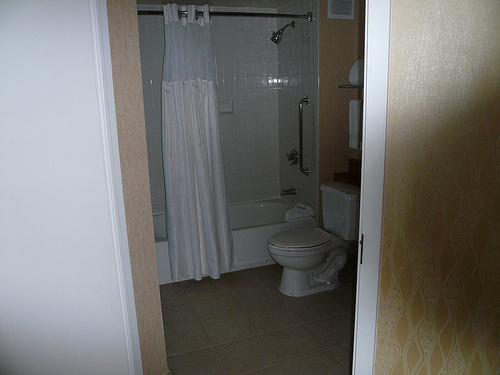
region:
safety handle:
[295, 92, 311, 177]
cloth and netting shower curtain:
[160, 3, 237, 283]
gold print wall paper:
[373, 0, 498, 374]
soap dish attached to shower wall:
[216, 97, 233, 114]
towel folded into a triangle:
[281, 200, 316, 225]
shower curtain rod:
[136, 9, 312, 21]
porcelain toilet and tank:
[265, 177, 358, 297]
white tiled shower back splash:
[136, 2, 321, 214]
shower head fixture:
[266, 18, 298, 47]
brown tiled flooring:
[159, 260, 357, 374]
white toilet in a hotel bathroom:
[285, 235, 342, 288]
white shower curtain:
[167, 7, 207, 265]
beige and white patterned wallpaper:
[404, 136, 481, 365]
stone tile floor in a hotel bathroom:
[180, 296, 342, 348]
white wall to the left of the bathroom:
[13, 84, 94, 364]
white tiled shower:
[235, 55, 277, 181]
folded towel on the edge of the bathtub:
[284, 202, 315, 219]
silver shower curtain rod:
[209, 9, 314, 19]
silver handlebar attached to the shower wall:
[299, 97, 308, 176]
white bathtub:
[235, 202, 266, 254]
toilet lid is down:
[266, 219, 332, 259]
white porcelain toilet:
[260, 155, 365, 317]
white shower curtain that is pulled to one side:
[148, 9, 256, 284]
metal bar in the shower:
[293, 96, 314, 179]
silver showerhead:
[265, 21, 297, 47]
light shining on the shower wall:
[262, 73, 292, 90]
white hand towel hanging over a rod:
[339, 96, 366, 149]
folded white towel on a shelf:
[337, 56, 365, 92]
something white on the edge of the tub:
[275, 196, 317, 222]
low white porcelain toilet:
[255, 219, 357, 327]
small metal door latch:
[354, 218, 374, 273]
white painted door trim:
[340, 7, 410, 373]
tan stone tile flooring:
[186, 292, 308, 369]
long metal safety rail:
[287, 94, 314, 179]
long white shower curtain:
[147, 7, 241, 291]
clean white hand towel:
[340, 97, 362, 149]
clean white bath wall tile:
[232, 43, 306, 110]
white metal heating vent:
[319, 1, 357, 33]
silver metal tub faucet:
[273, 183, 299, 201]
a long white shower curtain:
[155, 43, 240, 276]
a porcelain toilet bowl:
[264, 221, 343, 297]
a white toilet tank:
[316, 174, 357, 239]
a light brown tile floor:
[177, 283, 328, 369]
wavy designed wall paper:
[386, 138, 488, 368]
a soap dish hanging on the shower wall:
[218, 99, 238, 114]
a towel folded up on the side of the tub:
[280, 199, 315, 224]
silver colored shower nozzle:
[265, 18, 300, 45]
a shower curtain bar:
[141, 6, 311, 22]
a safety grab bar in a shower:
[291, 95, 316, 175]